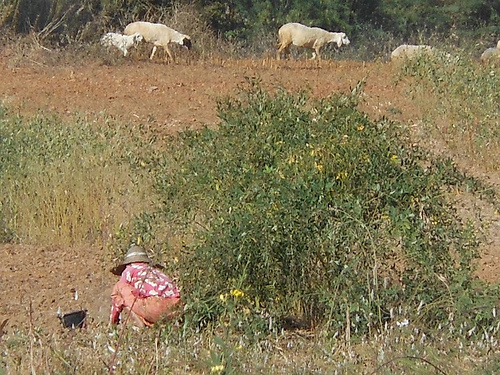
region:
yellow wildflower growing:
[209, 272, 259, 315]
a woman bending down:
[90, 241, 196, 340]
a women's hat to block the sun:
[110, 235, 165, 280]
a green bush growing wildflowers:
[183, 90, 444, 347]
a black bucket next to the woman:
[52, 305, 103, 346]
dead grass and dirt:
[3, 57, 200, 177]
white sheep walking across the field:
[270, 13, 367, 73]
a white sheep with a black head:
[126, 19, 196, 60]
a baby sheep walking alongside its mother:
[96, 24, 147, 58]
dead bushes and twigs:
[0, 0, 104, 58]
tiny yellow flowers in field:
[218, 285, 260, 309]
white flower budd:
[338, 291, 453, 358]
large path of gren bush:
[182, 154, 277, 251]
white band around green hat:
[116, 239, 151, 259]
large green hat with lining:
[85, 232, 191, 282]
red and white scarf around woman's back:
[125, 258, 187, 305]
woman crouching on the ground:
[62, 222, 224, 357]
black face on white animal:
[181, 29, 223, 76]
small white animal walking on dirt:
[80, 24, 152, 57]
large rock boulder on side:
[393, 35, 470, 74]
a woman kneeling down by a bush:
[106, 241, 184, 333]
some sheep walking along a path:
[97, 12, 497, 68]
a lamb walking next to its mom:
[96, 27, 146, 59]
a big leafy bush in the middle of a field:
[176, 103, 456, 330]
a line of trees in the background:
[5, 0, 497, 60]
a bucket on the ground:
[51, 305, 89, 328]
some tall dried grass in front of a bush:
[8, 145, 161, 240]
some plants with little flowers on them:
[175, 308, 494, 368]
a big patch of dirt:
[15, 66, 195, 117]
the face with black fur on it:
[181, 32, 191, 50]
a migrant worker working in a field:
[31, 232, 199, 347]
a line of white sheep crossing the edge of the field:
[100, 13, 483, 82]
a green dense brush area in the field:
[211, 125, 408, 280]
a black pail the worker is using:
[49, 304, 93, 342]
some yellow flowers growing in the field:
[212, 290, 244, 306]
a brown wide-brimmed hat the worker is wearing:
[108, 244, 166, 269]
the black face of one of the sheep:
[181, 37, 192, 49]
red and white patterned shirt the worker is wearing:
[125, 265, 175, 298]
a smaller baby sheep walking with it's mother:
[93, 31, 145, 57]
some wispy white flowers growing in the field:
[362, 318, 488, 353]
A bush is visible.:
[184, 71, 434, 255]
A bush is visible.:
[197, 108, 451, 373]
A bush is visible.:
[205, 177, 373, 367]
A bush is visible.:
[220, 81, 361, 298]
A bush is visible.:
[235, 174, 347, 319]